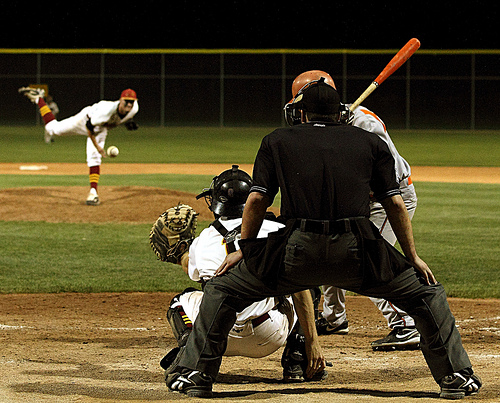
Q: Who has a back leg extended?
A: The pitcher.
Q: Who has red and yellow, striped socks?
A: The pitcher.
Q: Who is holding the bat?
A: The batter.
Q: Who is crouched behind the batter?
A: The catcher.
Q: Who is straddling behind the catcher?
A: The umpire.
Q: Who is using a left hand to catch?
A: The catcher.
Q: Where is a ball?
A: In the air.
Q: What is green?
A: Grass.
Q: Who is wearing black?
A: Umpire.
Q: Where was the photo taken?
A: At a baseball game.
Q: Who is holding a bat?
A: The batter.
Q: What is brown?
A: Dirt.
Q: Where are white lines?
A: On the dirt.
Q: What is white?
A: Pitcher's uniform.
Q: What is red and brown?
A: Bat.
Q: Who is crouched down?
A: The catcher.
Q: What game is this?
A: Baseball.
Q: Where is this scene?
A: Baseball field.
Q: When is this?
A: Night.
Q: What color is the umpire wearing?
A: Black.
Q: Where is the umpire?
A: Behind the catcher.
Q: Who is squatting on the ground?
A: Catcher.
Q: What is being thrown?
A: Baseball.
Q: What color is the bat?
A: Red and brown.